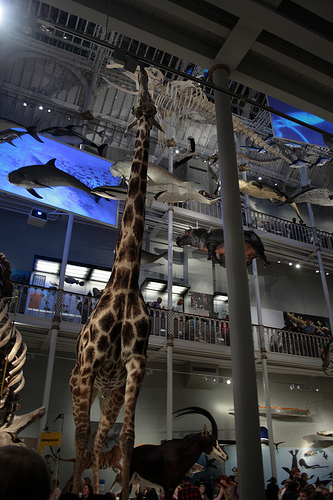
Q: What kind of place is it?
A: It is a museum.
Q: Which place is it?
A: It is a museum.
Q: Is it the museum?
A: Yes, it is the museum.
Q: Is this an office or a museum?
A: It is a museum.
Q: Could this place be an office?
A: No, it is a museum.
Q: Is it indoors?
A: Yes, it is indoors.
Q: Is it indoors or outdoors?
A: It is indoors.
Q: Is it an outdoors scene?
A: No, it is indoors.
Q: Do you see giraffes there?
A: Yes, there is a giraffe.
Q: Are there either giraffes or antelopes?
A: Yes, there is a giraffe.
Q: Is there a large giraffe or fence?
A: Yes, there is a large giraffe.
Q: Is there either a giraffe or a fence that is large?
A: Yes, the giraffe is large.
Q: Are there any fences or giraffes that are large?
A: Yes, the giraffe is large.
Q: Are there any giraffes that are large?
A: Yes, there is a large giraffe.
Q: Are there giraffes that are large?
A: Yes, there is a giraffe that is large.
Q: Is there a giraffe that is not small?
A: Yes, there is a large giraffe.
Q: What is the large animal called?
A: The animal is a giraffe.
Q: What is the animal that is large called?
A: The animal is a giraffe.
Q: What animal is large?
A: The animal is a giraffe.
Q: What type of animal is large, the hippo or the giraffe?
A: The giraffe is large.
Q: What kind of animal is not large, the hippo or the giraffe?
A: The hippo is not large.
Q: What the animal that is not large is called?
A: The animal is a hippo.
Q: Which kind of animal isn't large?
A: The animal is a hippo.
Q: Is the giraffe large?
A: Yes, the giraffe is large.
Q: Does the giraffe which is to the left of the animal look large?
A: Yes, the giraffe is large.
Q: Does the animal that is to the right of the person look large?
A: Yes, the giraffe is large.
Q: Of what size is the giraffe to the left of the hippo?
A: The giraffe is large.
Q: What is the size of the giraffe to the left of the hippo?
A: The giraffe is large.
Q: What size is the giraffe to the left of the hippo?
A: The giraffe is large.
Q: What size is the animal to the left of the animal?
A: The giraffe is large.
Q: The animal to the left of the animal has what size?
A: The giraffe is large.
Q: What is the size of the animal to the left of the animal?
A: The giraffe is large.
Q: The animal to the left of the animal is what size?
A: The giraffe is large.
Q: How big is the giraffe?
A: The giraffe is large.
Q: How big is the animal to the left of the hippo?
A: The giraffe is large.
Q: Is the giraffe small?
A: No, the giraffe is large.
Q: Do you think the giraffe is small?
A: No, the giraffe is large.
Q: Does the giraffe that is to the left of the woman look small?
A: No, the giraffe is large.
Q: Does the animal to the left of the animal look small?
A: No, the giraffe is large.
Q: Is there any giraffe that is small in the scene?
A: No, there is a giraffe but it is large.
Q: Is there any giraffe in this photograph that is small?
A: No, there is a giraffe but it is large.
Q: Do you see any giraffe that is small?
A: No, there is a giraffe but it is large.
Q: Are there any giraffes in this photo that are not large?
A: No, there is a giraffe but it is large.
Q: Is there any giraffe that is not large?
A: No, there is a giraffe but it is large.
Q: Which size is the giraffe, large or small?
A: The giraffe is large.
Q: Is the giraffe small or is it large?
A: The giraffe is large.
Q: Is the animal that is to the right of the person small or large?
A: The giraffe is large.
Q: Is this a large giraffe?
A: Yes, this is a large giraffe.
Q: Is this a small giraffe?
A: No, this is a large giraffe.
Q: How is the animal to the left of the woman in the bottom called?
A: The animal is a giraffe.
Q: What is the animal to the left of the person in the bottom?
A: The animal is a giraffe.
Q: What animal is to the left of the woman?
A: The animal is a giraffe.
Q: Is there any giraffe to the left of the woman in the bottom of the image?
A: Yes, there is a giraffe to the left of the woman.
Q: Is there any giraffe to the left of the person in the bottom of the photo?
A: Yes, there is a giraffe to the left of the woman.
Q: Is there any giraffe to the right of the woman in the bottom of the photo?
A: No, the giraffe is to the left of the woman.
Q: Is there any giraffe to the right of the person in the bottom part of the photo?
A: No, the giraffe is to the left of the woman.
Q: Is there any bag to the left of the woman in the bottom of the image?
A: No, there is a giraffe to the left of the woman.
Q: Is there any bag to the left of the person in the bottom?
A: No, there is a giraffe to the left of the woman.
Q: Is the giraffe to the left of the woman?
A: Yes, the giraffe is to the left of the woman.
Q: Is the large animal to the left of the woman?
A: Yes, the giraffe is to the left of the woman.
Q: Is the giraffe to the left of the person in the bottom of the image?
A: Yes, the giraffe is to the left of the woman.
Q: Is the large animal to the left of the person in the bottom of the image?
A: Yes, the giraffe is to the left of the woman.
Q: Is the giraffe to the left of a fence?
A: No, the giraffe is to the left of the woman.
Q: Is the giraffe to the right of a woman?
A: No, the giraffe is to the left of a woman.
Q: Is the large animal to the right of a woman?
A: No, the giraffe is to the left of a woman.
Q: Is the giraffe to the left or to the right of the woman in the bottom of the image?
A: The giraffe is to the left of the woman.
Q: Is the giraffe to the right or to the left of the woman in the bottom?
A: The giraffe is to the left of the woman.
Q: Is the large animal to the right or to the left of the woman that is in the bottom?
A: The giraffe is to the left of the woman.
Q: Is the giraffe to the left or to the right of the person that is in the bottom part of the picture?
A: The giraffe is to the left of the woman.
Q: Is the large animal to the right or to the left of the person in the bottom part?
A: The giraffe is to the left of the woman.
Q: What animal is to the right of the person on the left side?
A: The animal is a giraffe.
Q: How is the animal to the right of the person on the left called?
A: The animal is a giraffe.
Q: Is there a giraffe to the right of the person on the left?
A: Yes, there is a giraffe to the right of the person.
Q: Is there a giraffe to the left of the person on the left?
A: No, the giraffe is to the right of the person.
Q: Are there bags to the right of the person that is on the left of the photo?
A: No, there is a giraffe to the right of the person.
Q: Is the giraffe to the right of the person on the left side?
A: Yes, the giraffe is to the right of the person.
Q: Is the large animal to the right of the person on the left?
A: Yes, the giraffe is to the right of the person.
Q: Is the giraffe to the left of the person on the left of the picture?
A: No, the giraffe is to the right of the person.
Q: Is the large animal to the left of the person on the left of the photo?
A: No, the giraffe is to the right of the person.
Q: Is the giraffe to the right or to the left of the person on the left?
A: The giraffe is to the right of the person.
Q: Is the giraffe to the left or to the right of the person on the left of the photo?
A: The giraffe is to the right of the person.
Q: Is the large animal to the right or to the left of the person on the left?
A: The giraffe is to the right of the person.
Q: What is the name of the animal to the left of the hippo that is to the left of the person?
A: The animal is a giraffe.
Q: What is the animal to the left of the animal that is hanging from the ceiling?
A: The animal is a giraffe.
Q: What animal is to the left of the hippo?
A: The animal is a giraffe.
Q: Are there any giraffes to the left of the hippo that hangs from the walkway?
A: Yes, there is a giraffe to the left of the hippo.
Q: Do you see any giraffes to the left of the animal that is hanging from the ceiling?
A: Yes, there is a giraffe to the left of the hippo.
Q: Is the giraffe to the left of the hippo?
A: Yes, the giraffe is to the left of the hippo.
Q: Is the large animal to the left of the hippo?
A: Yes, the giraffe is to the left of the hippo.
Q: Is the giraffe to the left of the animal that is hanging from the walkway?
A: Yes, the giraffe is to the left of the hippo.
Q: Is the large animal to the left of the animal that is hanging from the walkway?
A: Yes, the giraffe is to the left of the hippo.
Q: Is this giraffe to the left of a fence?
A: No, the giraffe is to the left of the hippo.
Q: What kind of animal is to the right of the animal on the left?
A: The animal is a giraffe.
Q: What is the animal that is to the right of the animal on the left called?
A: The animal is a giraffe.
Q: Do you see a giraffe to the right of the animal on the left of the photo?
A: Yes, there is a giraffe to the right of the animal.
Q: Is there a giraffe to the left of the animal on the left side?
A: No, the giraffe is to the right of the animal.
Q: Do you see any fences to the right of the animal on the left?
A: No, there is a giraffe to the right of the animal.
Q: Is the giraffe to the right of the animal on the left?
A: Yes, the giraffe is to the right of the animal.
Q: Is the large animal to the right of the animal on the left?
A: Yes, the giraffe is to the right of the animal.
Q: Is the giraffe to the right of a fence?
A: No, the giraffe is to the right of the animal.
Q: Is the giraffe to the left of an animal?
A: No, the giraffe is to the right of an animal.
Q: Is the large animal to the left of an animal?
A: No, the giraffe is to the right of an animal.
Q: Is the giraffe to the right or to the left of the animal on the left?
A: The giraffe is to the right of the animal.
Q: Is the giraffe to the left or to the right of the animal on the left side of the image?
A: The giraffe is to the right of the animal.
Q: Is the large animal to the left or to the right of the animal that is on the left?
A: The giraffe is to the right of the animal.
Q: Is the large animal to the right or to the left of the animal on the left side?
A: The giraffe is to the right of the animal.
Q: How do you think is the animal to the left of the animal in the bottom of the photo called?
A: The animal is a giraffe.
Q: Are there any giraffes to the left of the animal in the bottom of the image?
A: Yes, there is a giraffe to the left of the animal.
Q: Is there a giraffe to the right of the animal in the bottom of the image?
A: No, the giraffe is to the left of the animal.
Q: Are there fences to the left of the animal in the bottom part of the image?
A: No, there is a giraffe to the left of the animal.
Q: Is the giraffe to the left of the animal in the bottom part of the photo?
A: Yes, the giraffe is to the left of the animal.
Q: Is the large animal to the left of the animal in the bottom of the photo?
A: Yes, the giraffe is to the left of the animal.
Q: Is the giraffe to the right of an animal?
A: No, the giraffe is to the left of an animal.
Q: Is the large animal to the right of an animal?
A: No, the giraffe is to the left of an animal.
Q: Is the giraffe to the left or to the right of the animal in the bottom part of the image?
A: The giraffe is to the left of the animal.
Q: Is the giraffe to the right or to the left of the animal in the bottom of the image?
A: The giraffe is to the left of the animal.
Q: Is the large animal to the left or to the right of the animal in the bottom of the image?
A: The giraffe is to the left of the animal.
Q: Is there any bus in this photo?
A: No, there are no buses.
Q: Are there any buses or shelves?
A: No, there are no buses or shelves.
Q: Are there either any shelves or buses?
A: No, there are no buses or shelves.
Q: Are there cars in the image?
A: No, there are no cars.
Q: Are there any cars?
A: No, there are no cars.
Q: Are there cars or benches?
A: No, there are no cars or benches.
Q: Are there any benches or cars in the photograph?
A: No, there are no cars or benches.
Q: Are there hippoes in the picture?
A: Yes, there is a hippo.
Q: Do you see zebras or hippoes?
A: Yes, there is a hippo.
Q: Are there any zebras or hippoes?
A: Yes, there is a hippo.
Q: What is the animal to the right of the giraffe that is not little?
A: The animal is a hippo.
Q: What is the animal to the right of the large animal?
A: The animal is a hippo.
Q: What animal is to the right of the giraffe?
A: The animal is a hippo.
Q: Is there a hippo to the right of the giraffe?
A: Yes, there is a hippo to the right of the giraffe.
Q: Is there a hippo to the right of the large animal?
A: Yes, there is a hippo to the right of the giraffe.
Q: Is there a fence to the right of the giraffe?
A: No, there is a hippo to the right of the giraffe.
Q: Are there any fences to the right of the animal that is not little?
A: No, there is a hippo to the right of the giraffe.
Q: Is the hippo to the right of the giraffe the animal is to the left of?
A: Yes, the hippo is to the right of the giraffe.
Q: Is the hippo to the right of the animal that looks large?
A: Yes, the hippo is to the right of the giraffe.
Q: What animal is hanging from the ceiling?
A: The hippo is hanging from the ceiling.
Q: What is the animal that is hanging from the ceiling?
A: The animal is a hippo.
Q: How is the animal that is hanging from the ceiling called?
A: The animal is a hippo.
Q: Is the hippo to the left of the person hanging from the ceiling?
A: Yes, the hippo is hanging from the ceiling.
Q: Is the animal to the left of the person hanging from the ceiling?
A: Yes, the hippo is hanging from the ceiling.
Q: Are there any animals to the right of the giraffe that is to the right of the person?
A: Yes, there is an animal to the right of the giraffe.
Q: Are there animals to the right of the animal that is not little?
A: Yes, there is an animal to the right of the giraffe.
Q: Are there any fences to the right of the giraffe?
A: No, there is an animal to the right of the giraffe.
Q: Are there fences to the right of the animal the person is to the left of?
A: No, there is an animal to the right of the giraffe.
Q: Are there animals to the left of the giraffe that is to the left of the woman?
A: Yes, there is an animal to the left of the giraffe.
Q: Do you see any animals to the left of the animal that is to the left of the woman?
A: Yes, there is an animal to the left of the giraffe.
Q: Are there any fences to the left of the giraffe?
A: No, there is an animal to the left of the giraffe.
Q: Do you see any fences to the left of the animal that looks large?
A: No, there is an animal to the left of the giraffe.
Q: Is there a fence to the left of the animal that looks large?
A: No, there is an animal to the left of the giraffe.